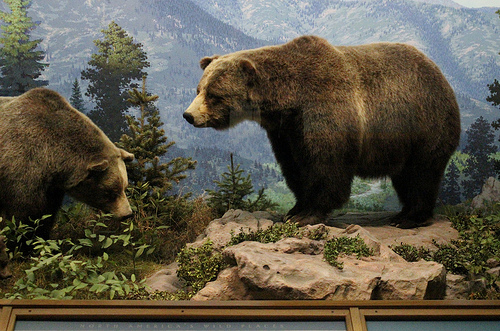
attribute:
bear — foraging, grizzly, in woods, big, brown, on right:
[182, 35, 462, 230]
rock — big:
[139, 208, 499, 299]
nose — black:
[182, 112, 195, 125]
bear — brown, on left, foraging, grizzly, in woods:
[0, 88, 136, 237]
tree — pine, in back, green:
[0, 0, 48, 97]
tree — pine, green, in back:
[70, 78, 85, 113]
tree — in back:
[80, 20, 150, 143]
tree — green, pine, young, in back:
[115, 72, 197, 200]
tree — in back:
[460, 117, 499, 199]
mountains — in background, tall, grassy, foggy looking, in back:
[1, 2, 499, 205]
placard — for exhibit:
[11, 318, 346, 329]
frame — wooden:
[1, 298, 499, 329]